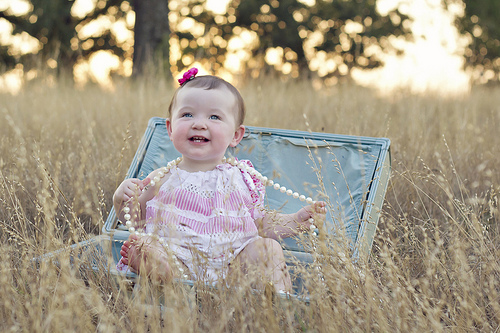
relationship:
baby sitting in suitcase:
[110, 67, 327, 294] [136, 126, 403, 268]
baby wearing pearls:
[110, 67, 327, 294] [243, 158, 328, 222]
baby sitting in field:
[110, 67, 327, 294] [3, 80, 499, 330]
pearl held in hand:
[120, 146, 322, 266] [295, 202, 327, 234]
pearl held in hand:
[120, 146, 322, 266] [112, 173, 152, 205]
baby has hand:
[110, 67, 327, 294] [295, 202, 327, 234]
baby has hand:
[110, 67, 327, 294] [112, 173, 152, 205]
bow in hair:
[177, 67, 197, 86] [158, 74, 253, 138]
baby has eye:
[110, 67, 327, 294] [180, 109, 193, 121]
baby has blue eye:
[110, 67, 327, 294] [208, 113, 224, 121]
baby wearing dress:
[110, 67, 327, 294] [150, 167, 262, 255]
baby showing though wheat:
[110, 67, 327, 294] [2, 90, 498, 332]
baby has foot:
[110, 67, 327, 294] [114, 234, 170, 281]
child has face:
[103, 72, 325, 307] [173, 77, 232, 155]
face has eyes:
[173, 77, 232, 155] [176, 109, 221, 119]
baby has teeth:
[110, 67, 327, 294] [190, 133, 207, 145]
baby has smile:
[110, 67, 327, 294] [179, 132, 212, 147]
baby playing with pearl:
[110, 67, 327, 294] [120, 146, 322, 280]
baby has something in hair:
[110, 67, 327, 294] [169, 75, 244, 125]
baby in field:
[110, 67, 327, 294] [3, 80, 499, 330]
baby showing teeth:
[110, 67, 327, 294] [184, 135, 204, 145]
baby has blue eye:
[110, 67, 327, 294] [208, 113, 219, 123]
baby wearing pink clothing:
[110, 67, 327, 294] [141, 161, 263, 281]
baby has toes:
[110, 67, 327, 294] [92, 221, 201, 292]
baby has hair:
[113, 74, 324, 286] [166, 74, 248, 134]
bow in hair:
[177, 67, 197, 86] [166, 74, 248, 134]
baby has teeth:
[110, 67, 327, 294] [189, 133, 209, 140]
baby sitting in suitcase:
[110, 67, 327, 294] [44, 116, 395, 316]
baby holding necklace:
[110, 67, 327, 294] [118, 146, 329, 276]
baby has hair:
[113, 74, 324, 286] [169, 75, 244, 125]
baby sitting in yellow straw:
[110, 67, 327, 294] [3, 160, 494, 331]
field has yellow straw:
[3, 80, 499, 330] [3, 160, 494, 331]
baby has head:
[110, 67, 327, 294] [165, 75, 245, 161]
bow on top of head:
[177, 67, 197, 86] [165, 75, 245, 161]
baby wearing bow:
[110, 67, 327, 294] [177, 67, 197, 86]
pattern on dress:
[145, 189, 257, 238] [140, 145, 294, 302]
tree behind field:
[448, 4, 499, 91] [15, 97, 498, 290]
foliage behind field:
[164, 2, 431, 63] [15, 97, 498, 290]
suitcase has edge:
[44, 116, 395, 316] [245, 131, 383, 151]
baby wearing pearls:
[110, 67, 327, 294] [145, 156, 316, 204]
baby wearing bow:
[110, 67, 327, 294] [142, 63, 246, 104]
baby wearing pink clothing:
[110, 67, 327, 294] [137, 161, 267, 281]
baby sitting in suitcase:
[110, 67, 327, 294] [25, 99, 396, 308]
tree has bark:
[115, 3, 193, 73] [135, 6, 169, 85]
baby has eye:
[110, 67, 327, 294] [208, 115, 224, 122]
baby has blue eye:
[110, 67, 327, 294] [180, 110, 195, 118]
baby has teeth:
[110, 67, 327, 294] [188, 135, 205, 142]